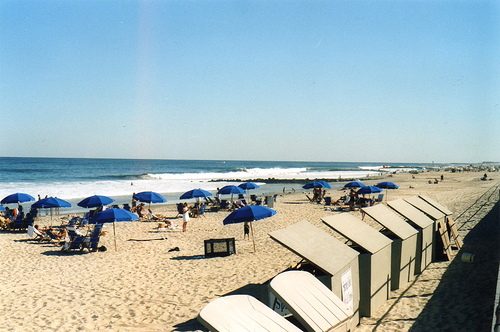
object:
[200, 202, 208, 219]
people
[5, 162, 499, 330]
beach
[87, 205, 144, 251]
umbrella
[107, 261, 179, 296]
sand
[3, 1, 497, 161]
sky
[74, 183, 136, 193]
waves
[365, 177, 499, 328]
shadow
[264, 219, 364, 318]
bins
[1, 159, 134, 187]
water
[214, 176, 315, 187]
area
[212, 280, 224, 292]
footprints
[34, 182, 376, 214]
shore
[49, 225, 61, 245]
person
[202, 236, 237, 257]
playpen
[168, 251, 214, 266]
shadow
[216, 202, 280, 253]
umbrella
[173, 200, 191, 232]
child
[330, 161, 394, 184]
retaining wall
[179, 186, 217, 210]
umbrellas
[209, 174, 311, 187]
jetty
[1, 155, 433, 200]
ocean